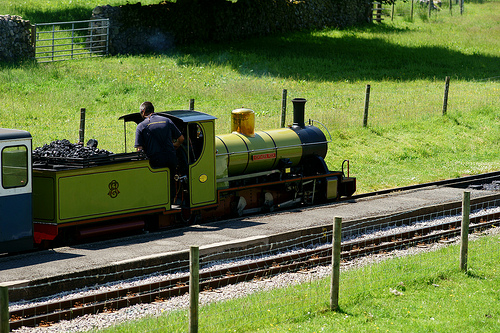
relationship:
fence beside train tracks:
[5, 190, 498, 332] [9, 168, 499, 332]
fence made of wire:
[5, 190, 498, 332] [206, 233, 328, 323]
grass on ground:
[14, 25, 497, 180] [3, 18, 491, 328]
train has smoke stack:
[3, 90, 358, 253] [291, 95, 310, 125]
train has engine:
[3, 90, 358, 253] [130, 89, 358, 231]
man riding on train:
[133, 102, 184, 206] [3, 90, 358, 253]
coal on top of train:
[32, 135, 107, 164] [3, 90, 358, 253]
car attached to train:
[0, 125, 36, 251] [3, 90, 358, 253]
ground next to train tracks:
[3, 18, 491, 328] [9, 168, 499, 332]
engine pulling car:
[130, 89, 358, 231] [0, 125, 36, 251]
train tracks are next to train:
[9, 168, 499, 332] [3, 90, 358, 253]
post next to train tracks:
[362, 82, 374, 131] [9, 168, 499, 332]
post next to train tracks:
[329, 215, 342, 312] [9, 168, 499, 332]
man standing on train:
[133, 102, 184, 206] [3, 90, 358, 253]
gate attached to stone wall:
[34, 15, 110, 64] [94, 0, 376, 61]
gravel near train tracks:
[49, 294, 241, 330] [9, 168, 499, 332]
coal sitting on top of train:
[32, 135, 107, 164] [3, 90, 358, 253]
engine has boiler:
[130, 89, 358, 231] [228, 107, 259, 136]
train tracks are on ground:
[9, 168, 499, 332] [3, 18, 491, 328]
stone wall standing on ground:
[94, 0, 376, 61] [3, 18, 491, 328]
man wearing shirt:
[133, 102, 184, 206] [134, 118, 185, 156]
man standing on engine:
[133, 102, 184, 206] [130, 89, 358, 231]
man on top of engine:
[133, 102, 184, 206] [130, 89, 358, 231]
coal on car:
[32, 135, 107, 164] [28, 148, 164, 241]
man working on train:
[133, 102, 184, 206] [3, 90, 358, 253]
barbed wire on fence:
[199, 225, 332, 260] [5, 190, 498, 332]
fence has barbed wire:
[5, 190, 498, 332] [199, 225, 332, 260]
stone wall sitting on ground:
[94, 0, 376, 61] [3, 18, 491, 328]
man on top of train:
[133, 102, 184, 206] [3, 90, 358, 253]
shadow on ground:
[153, 41, 500, 87] [3, 18, 491, 328]